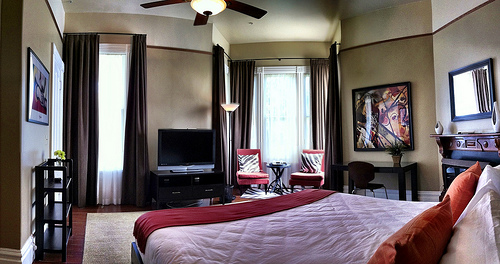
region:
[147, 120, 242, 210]
The television is on the table.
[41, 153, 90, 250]
A flower is on the bookstand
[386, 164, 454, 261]
The pillows on the bed are orange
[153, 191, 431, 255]
The comforter on the bed is white.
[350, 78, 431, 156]
A painting on the wall.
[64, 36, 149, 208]
The curtains are open.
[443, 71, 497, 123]
A mirror on the wall.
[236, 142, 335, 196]
Two chairs sit in front of the window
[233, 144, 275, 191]
The chair has a pillow on it.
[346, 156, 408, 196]
A chair in front of the desk.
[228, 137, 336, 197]
two pink chairs and a table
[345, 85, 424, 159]
artwork in black frame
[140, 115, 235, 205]
television on a stand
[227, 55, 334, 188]
window with brown curtains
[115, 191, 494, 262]
bed has pink bedspread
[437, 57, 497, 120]
curtain reflected in mirror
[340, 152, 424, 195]
chair and small workspace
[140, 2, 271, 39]
ceiling fan with light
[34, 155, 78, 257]
shelving unit is black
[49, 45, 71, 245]
door is painted white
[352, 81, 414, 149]
Framed modern painting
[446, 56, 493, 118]
Black framed mirror on the wall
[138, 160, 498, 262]
Bed with red and white bedding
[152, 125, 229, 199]
Large flat television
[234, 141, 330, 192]
Red occasional chairs with a black table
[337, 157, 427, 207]
Black console table with a chair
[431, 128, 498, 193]
Black and brown fireplace mantel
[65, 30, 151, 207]
Brown curtains and white sheers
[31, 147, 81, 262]
Black three level shelf with a flower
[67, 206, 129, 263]
Hardwood floor with a white area rug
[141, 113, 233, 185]
flat screen tv on table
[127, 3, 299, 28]
ceiling fan hanging from ceiling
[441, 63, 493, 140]
mirror hanging above mantel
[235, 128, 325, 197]
two chairs in front of window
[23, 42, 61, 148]
frames photo hanging on wall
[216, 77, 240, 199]
floor lamp behind chair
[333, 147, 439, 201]
desk and chair by wall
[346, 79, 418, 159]
framed art on the wall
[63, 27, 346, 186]
brown drapes on the windows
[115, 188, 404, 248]
pink coverlet on end of bed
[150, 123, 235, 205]
a tv and tv stand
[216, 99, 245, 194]
a floor lamp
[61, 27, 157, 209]
window with white and brown curtains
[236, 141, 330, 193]
two red chairs on either side of a small table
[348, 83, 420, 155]
a modern, abstract painting on the wall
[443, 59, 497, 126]
a larger wall mirror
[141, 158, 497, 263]
a bed with white and red covers and orange and white pillows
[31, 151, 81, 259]
a small bookcase with three shelves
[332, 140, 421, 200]
a black chair in front of a black desk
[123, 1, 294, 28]
ceiling fan